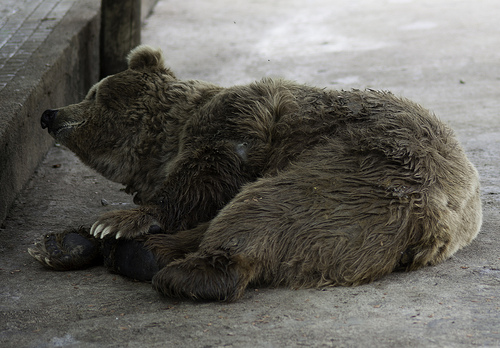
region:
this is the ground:
[298, 298, 390, 339]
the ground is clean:
[306, 301, 368, 327]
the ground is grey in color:
[317, 307, 361, 336]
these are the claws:
[85, 220, 122, 240]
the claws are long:
[72, 225, 132, 240]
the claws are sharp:
[80, 218, 125, 239]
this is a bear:
[27, 25, 492, 323]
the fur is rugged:
[336, 171, 383, 206]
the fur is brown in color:
[280, 170, 350, 230]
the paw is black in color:
[62, 233, 79, 249]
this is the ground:
[326, 48, 466, 80]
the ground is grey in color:
[255, 300, 391, 345]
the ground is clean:
[266, 291, 392, 336]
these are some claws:
[79, 218, 131, 238]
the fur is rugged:
[294, 193, 362, 243]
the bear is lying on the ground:
[33, 28, 496, 301]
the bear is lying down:
[11, 65, 472, 326]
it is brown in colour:
[20, 20, 477, 305]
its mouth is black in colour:
[14, 99, 75, 134]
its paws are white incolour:
[47, 201, 152, 262]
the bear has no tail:
[350, 183, 481, 311]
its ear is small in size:
[109, 36, 180, 96]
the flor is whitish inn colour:
[293, 280, 456, 345]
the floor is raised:
[2, 18, 82, 75]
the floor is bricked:
[4, 5, 90, 84]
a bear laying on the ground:
[31, 33, 476, 310]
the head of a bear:
[29, 37, 239, 201]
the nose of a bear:
[28, 105, 67, 154]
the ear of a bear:
[123, 30, 186, 80]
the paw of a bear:
[51, 171, 193, 268]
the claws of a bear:
[81, 214, 151, 244]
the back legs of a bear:
[113, 113, 430, 310]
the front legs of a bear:
[27, 118, 277, 270]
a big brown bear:
[53, 30, 499, 302]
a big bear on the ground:
[38, 53, 483, 312]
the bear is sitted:
[44, 50, 488, 313]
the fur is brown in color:
[290, 142, 396, 229]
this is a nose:
[37, 103, 56, 129]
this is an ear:
[123, 43, 160, 68]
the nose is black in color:
[40, 107, 55, 127]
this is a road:
[376, 301, 451, 344]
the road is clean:
[385, 279, 462, 341]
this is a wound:
[218, 129, 257, 162]